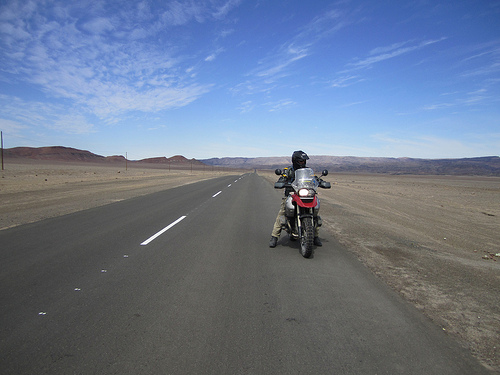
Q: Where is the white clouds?
A: In blue sky.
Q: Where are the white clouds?
A: In blue sky.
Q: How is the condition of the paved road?
A: Empty.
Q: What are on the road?
A: White lines.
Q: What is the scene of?
A: A quiet desert scene.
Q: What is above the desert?
A: A blue sky.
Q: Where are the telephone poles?
A: In the desert.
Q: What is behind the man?
A: Hills.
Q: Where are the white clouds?
A: In blue sky.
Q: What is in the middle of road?
A: Line.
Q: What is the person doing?
A: Riding motorcycle.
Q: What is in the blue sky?
A: White clouds.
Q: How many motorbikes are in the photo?
A: One.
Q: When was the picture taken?
A: Daytime.